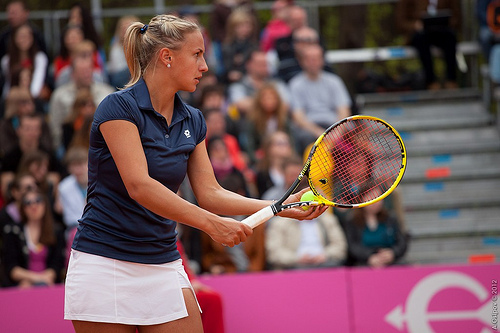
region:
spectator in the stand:
[13, 190, 68, 282]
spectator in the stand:
[48, 139, 95, 215]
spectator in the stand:
[4, 118, 45, 158]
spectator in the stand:
[358, 188, 408, 265]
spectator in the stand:
[290, 37, 365, 124]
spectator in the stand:
[256, 87, 286, 128]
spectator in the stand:
[201, 92, 240, 128]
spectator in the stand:
[64, 61, 107, 87]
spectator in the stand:
[11, 22, 38, 68]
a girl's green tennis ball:
[297, 188, 317, 206]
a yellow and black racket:
[241, 110, 412, 235]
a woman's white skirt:
[62, 253, 207, 326]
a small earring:
[165, 61, 173, 71]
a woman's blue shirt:
[71, 83, 213, 270]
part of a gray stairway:
[363, 98, 498, 261]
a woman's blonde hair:
[114, 9, 198, 96]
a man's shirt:
[291, 70, 351, 125]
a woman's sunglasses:
[22, 195, 43, 207]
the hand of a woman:
[198, 209, 255, 249]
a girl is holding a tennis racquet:
[112, 18, 452, 246]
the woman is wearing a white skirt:
[35, 222, 185, 303]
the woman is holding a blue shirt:
[102, 86, 269, 285]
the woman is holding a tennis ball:
[265, 138, 382, 261]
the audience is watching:
[230, 43, 470, 288]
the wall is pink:
[225, 273, 360, 328]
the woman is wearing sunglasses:
[14, 189, 64, 217]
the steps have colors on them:
[410, 130, 495, 270]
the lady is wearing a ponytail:
[112, 13, 258, 99]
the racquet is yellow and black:
[281, 99, 493, 229]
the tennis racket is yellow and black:
[239, 111, 410, 229]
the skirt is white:
[62, 241, 204, 320]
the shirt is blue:
[72, 79, 209, 266]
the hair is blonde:
[115, 11, 208, 97]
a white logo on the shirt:
[178, 123, 194, 143]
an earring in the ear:
[155, 44, 175, 69]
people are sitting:
[1, 5, 408, 286]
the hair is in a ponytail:
[110, 9, 157, 91]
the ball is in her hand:
[282, 185, 329, 222]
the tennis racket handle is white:
[233, 201, 277, 229]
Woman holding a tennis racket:
[61, 10, 411, 330]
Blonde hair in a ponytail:
[114, 8, 201, 94]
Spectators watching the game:
[1, 1, 413, 291]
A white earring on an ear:
[158, 44, 177, 75]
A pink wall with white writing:
[2, 260, 498, 331]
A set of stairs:
[357, 87, 498, 267]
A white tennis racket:
[61, 247, 205, 327]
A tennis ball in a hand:
[279, 181, 328, 224]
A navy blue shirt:
[67, 74, 208, 267]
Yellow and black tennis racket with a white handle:
[241, 113, 410, 233]